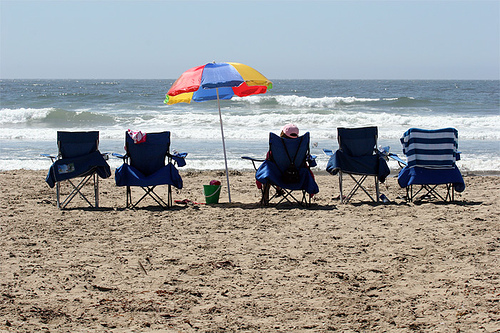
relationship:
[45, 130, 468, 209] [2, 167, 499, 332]
chairs on beach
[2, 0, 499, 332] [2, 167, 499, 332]
beach with beach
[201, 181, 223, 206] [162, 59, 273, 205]
sand pail under umbrella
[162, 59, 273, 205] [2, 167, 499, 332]
umbrella standing in beach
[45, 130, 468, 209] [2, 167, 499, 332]
five chairs on beach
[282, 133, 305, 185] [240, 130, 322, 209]
sack on chair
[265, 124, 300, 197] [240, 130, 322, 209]
person sitting in chair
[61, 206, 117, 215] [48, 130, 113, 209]
shadow cast by chair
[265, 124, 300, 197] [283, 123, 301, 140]
person wearing hat